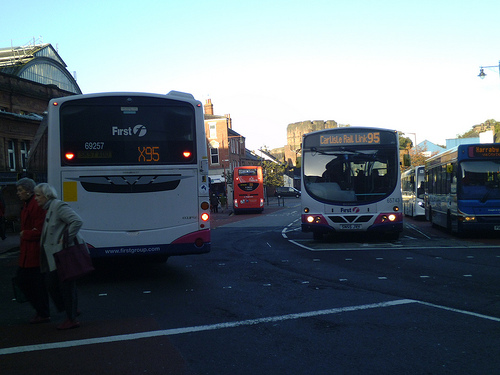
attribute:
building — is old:
[276, 114, 338, 167]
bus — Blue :
[420, 136, 498, 241]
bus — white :
[36, 74, 229, 262]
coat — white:
[40, 197, 85, 272]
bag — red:
[51, 227, 93, 273]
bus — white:
[293, 122, 410, 240]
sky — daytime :
[1, 0, 498, 147]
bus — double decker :
[228, 154, 268, 204]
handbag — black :
[52, 226, 99, 288]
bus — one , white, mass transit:
[27, 90, 214, 267]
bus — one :
[297, 127, 403, 243]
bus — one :
[418, 142, 497, 239]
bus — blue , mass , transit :
[427, 138, 497, 233]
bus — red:
[229, 162, 264, 213]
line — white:
[0, 298, 498, 357]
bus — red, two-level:
[224, 163, 270, 216]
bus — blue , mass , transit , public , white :
[302, 124, 404, 238]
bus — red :
[231, 165, 264, 213]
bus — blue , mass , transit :
[230, 161, 266, 211]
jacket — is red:
[20, 204, 40, 268]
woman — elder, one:
[33, 180, 99, 322]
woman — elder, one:
[10, 174, 50, 290]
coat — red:
[16, 194, 43, 259]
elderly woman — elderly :
[1, 175, 45, 324]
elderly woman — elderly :
[32, 184, 89, 317]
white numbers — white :
[82, 137, 104, 154]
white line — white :
[189, 294, 417, 334]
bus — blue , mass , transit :
[48, 91, 210, 253]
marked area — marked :
[211, 234, 483, 344]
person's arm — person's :
[59, 197, 81, 236]